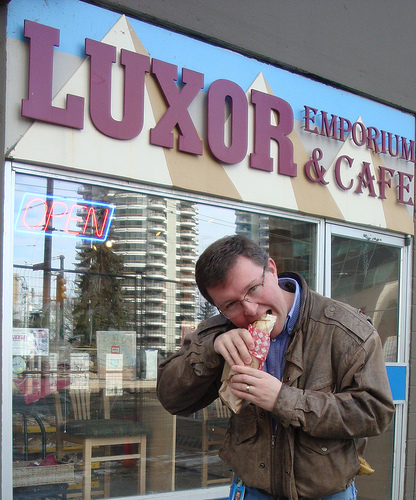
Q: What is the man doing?
A: Eating.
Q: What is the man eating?
A: A sandwich.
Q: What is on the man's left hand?
A: A ring.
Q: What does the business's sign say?
A: Luxor Emporium & Cafe.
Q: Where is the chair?
A: In the window.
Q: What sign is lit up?
A: The open sign.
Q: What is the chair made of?
A: Wood.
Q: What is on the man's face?
A: Glasses.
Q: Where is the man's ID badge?
A: Clipped to his pants.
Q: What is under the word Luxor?
A: Pyramids.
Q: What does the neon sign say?
A: OPEN.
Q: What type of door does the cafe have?
A: Glass.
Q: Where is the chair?
A: Inside cafe.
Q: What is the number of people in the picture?
A: One.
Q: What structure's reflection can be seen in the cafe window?
A: White building.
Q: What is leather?
A: Man's jacket.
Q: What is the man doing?
A: Eating.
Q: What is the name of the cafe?
A: LUXOR EMPORIUM & CAFE.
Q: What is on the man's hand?
A: Ring.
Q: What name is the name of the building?
A: Luxor Emporium and Cafe.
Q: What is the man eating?
A: Hot dog.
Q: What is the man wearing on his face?
A: Glasses.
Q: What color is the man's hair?
A: Brown.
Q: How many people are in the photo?
A: One.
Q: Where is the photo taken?
A: Restaurant.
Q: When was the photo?
A: Afternoon.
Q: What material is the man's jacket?
A: Leather.